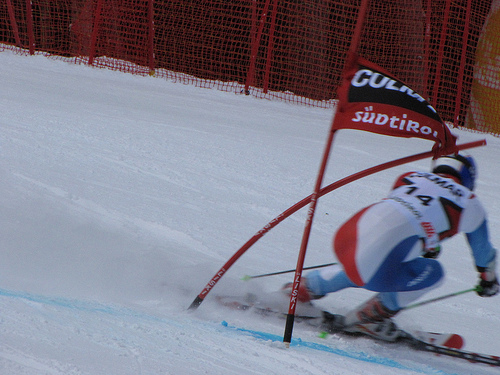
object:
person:
[264, 150, 499, 346]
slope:
[4, 45, 499, 373]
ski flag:
[259, 3, 460, 343]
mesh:
[2, 2, 499, 137]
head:
[429, 148, 479, 192]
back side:
[332, 217, 409, 294]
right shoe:
[345, 297, 402, 341]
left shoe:
[280, 272, 328, 318]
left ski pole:
[244, 245, 341, 298]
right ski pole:
[321, 280, 481, 337]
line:
[2, 283, 411, 372]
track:
[11, 165, 230, 271]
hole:
[142, 297, 167, 313]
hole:
[47, 357, 62, 371]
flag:
[336, 55, 458, 161]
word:
[353, 101, 443, 140]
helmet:
[433, 150, 477, 190]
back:
[391, 169, 480, 239]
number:
[404, 182, 434, 210]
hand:
[476, 278, 500, 297]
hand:
[425, 246, 441, 259]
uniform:
[301, 170, 496, 316]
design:
[363, 231, 442, 293]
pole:
[188, 135, 490, 315]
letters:
[199, 267, 226, 302]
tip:
[242, 274, 253, 284]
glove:
[477, 265, 499, 299]